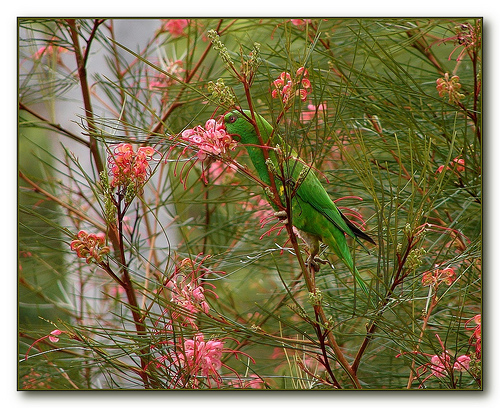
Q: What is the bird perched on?
A: Red branches.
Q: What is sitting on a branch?
A: Green bird.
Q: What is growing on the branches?
A: Thing long needle like leaves.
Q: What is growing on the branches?
A: Pink flowers.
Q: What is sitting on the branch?
A: Long bird with folded wings?.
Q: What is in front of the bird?
A: Long branch.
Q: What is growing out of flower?
A: Long and slender red growths.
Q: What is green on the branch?
A: A bird.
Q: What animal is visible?
A: Parrot.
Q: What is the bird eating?
A: Flowers.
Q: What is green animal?
A: Bird.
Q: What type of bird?
A: Parrot.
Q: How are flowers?
A: Curling.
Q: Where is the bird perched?
A: On a branch.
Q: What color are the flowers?
A: Pink.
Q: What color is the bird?
A: Green.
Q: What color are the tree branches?
A: Brown.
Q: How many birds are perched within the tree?
A: One.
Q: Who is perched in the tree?
A: The bird.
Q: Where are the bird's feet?
A: On the branch.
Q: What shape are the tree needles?
A: Long and thin.